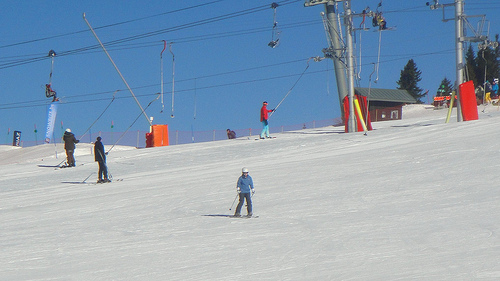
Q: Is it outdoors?
A: Yes, it is outdoors.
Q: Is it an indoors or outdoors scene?
A: It is outdoors.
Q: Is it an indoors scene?
A: No, it is outdoors.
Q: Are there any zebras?
A: No, there are no zebras.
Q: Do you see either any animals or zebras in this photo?
A: No, there are no zebras or animals.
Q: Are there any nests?
A: No, there are no nests.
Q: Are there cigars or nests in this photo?
A: No, there are no nests or cigars.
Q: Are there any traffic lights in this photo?
A: No, there are no traffic lights.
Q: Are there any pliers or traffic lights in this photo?
A: No, there are no traffic lights or pliers.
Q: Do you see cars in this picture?
A: No, there are no cars.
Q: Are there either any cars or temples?
A: No, there are no cars or temples.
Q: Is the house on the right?
A: Yes, the house is on the right of the image.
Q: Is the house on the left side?
A: No, the house is on the right of the image.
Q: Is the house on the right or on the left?
A: The house is on the right of the image.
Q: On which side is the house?
A: The house is on the right of the image.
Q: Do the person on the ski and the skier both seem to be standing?
A: Yes, both the person and the skier are standing.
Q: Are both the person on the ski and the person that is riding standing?
A: Yes, both the person and the skier are standing.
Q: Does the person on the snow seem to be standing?
A: Yes, the person is standing.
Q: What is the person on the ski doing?
A: The person is standing.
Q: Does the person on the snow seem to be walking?
A: No, the person is standing.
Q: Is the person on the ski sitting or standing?
A: The person is standing.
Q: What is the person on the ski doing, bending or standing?
A: The person is standing.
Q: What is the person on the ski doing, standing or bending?
A: The person is standing.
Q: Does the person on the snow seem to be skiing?
A: Yes, the person is skiing.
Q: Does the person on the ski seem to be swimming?
A: No, the person is skiing.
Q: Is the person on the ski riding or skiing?
A: The person is skiing.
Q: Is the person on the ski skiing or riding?
A: The person is skiing.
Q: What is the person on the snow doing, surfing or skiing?
A: The person is skiing.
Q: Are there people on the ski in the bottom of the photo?
A: Yes, there is a person on the ski.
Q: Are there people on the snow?
A: Yes, there is a person on the snow.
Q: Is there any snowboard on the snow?
A: No, there is a person on the snow.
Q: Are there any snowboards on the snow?
A: No, there is a person on the snow.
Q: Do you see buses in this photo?
A: No, there are no buses.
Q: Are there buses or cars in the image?
A: No, there are no buses or cars.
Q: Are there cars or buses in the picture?
A: No, there are no buses or cars.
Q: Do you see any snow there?
A: Yes, there is snow.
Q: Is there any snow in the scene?
A: Yes, there is snow.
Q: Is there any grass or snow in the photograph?
A: Yes, there is snow.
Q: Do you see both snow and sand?
A: No, there is snow but no sand.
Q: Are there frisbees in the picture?
A: No, there are no frisbees.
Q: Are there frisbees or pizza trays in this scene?
A: No, there are no frisbees or pizza trays.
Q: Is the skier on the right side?
A: Yes, the skier is on the right of the image.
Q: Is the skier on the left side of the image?
A: No, the skier is on the right of the image.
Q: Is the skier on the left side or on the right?
A: The skier is on the right of the image.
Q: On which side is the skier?
A: The skier is on the right of the image.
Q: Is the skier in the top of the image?
A: Yes, the skier is in the top of the image.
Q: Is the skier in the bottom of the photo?
A: No, the skier is in the top of the image.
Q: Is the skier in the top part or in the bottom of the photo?
A: The skier is in the top of the image.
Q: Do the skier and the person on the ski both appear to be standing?
A: Yes, both the skier and the person are standing.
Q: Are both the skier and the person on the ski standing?
A: Yes, both the skier and the person are standing.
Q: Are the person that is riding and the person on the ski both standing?
A: Yes, both the skier and the person are standing.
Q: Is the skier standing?
A: Yes, the skier is standing.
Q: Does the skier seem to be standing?
A: Yes, the skier is standing.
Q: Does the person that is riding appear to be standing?
A: Yes, the skier is standing.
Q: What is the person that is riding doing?
A: The skier is standing.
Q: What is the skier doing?
A: The skier is standing.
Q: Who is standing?
A: The skier is standing.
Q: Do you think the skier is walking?
A: No, the skier is standing.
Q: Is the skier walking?
A: No, the skier is standing.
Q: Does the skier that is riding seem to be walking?
A: No, the skier is standing.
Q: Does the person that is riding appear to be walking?
A: No, the skier is standing.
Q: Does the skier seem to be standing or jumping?
A: The skier is standing.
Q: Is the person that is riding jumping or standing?
A: The skier is standing.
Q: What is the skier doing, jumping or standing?
A: The skier is standing.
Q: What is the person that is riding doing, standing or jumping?
A: The skier is standing.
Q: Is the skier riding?
A: Yes, the skier is riding.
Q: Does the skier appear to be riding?
A: Yes, the skier is riding.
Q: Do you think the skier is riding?
A: Yes, the skier is riding.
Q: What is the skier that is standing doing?
A: The skier is riding.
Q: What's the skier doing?
A: The skier is riding.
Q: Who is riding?
A: The skier is riding.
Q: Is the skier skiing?
A: No, the skier is riding.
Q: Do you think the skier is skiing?
A: No, the skier is riding.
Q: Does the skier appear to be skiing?
A: No, the skier is riding.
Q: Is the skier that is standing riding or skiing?
A: The skier is riding.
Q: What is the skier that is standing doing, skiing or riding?
A: The skier is riding.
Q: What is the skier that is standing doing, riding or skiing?
A: The skier is riding.